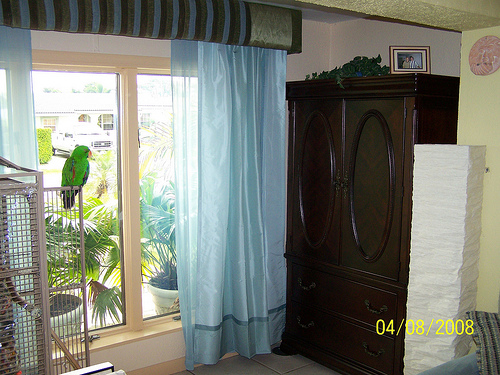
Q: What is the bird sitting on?
A: Its cage.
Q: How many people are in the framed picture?
A: Two.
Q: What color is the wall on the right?
A: Yellow.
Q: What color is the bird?
A: Green.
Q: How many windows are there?
A: Two.